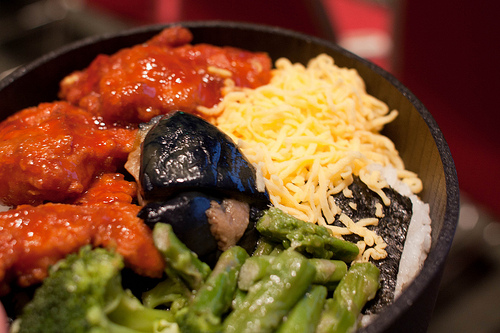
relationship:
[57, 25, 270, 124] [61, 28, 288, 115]
chicken on chicken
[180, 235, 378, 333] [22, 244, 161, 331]
green beans next to broccoli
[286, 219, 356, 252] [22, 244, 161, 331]
green beans next to broccoli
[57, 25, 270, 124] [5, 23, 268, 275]
chicken on chicken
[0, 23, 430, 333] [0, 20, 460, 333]
food in bowl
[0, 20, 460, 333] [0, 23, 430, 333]
bowl with food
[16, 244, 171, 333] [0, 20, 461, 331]
broccoli at one side of bowl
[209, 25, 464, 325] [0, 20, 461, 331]
rim of bowl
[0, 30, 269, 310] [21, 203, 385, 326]
food next to vegetables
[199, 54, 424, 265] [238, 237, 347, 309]
cheddar cheese touching vegetables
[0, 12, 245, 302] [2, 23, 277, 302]
chicken smothered in sauce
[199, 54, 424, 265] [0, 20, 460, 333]
cheddar cheese on side of bowl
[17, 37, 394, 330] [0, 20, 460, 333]
food in bowl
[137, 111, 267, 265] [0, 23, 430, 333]
food of food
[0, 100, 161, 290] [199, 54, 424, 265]
chicken of cheddar cheese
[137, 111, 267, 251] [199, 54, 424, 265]
food of cheddar cheese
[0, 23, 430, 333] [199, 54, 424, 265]
food of cheddar cheese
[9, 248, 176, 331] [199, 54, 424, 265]
food of cheddar cheese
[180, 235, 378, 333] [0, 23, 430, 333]
green beans of food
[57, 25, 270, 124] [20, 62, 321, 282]
chicken of food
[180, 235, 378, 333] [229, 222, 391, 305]
green beans of food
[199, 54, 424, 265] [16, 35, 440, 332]
cheddar cheese side of dish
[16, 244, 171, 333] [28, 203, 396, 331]
broccoli of broccoli